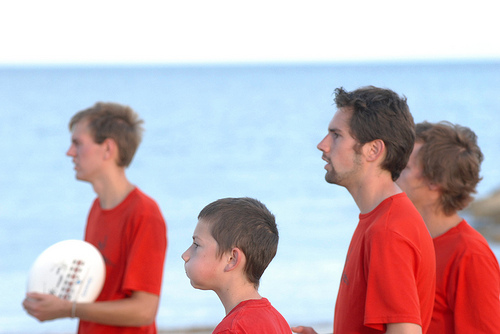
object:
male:
[22, 100, 167, 333]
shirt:
[77, 184, 168, 333]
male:
[181, 196, 291, 333]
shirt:
[211, 296, 292, 332]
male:
[317, 84, 437, 333]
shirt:
[333, 191, 437, 333]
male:
[394, 119, 499, 333]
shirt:
[427, 218, 500, 333]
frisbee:
[27, 239, 106, 304]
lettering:
[48, 258, 82, 301]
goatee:
[324, 169, 341, 184]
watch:
[70, 302, 77, 318]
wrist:
[67, 301, 86, 319]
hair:
[329, 85, 418, 182]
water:
[0, 59, 499, 333]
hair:
[69, 100, 146, 168]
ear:
[224, 247, 242, 272]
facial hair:
[321, 152, 363, 185]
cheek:
[186, 255, 216, 286]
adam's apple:
[93, 181, 104, 196]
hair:
[197, 196, 280, 290]